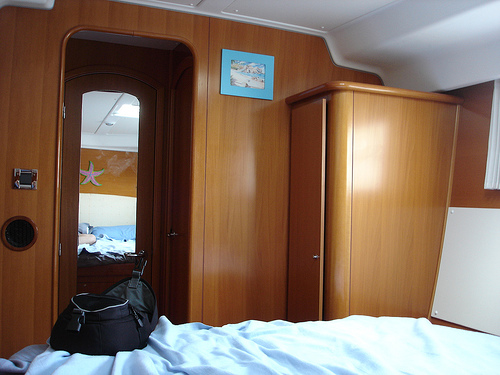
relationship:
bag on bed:
[49, 257, 159, 357] [0, 313, 499, 374]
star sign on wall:
[79, 160, 106, 187] [78, 133, 139, 226]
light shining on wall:
[234, 137, 254, 197] [0, 0, 384, 360]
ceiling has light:
[81, 89, 141, 136] [116, 103, 140, 120]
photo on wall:
[229, 58, 264, 90] [0, 0, 384, 360]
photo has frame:
[229, 58, 264, 90] [220, 48, 275, 101]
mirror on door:
[78, 88, 140, 295] [58, 71, 157, 295]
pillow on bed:
[91, 225, 137, 240] [77, 232, 137, 267]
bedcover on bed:
[24, 314, 499, 374] [0, 313, 499, 374]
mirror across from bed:
[78, 88, 140, 295] [0, 313, 499, 374]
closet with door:
[285, 80, 464, 322] [287, 98, 327, 322]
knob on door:
[312, 253, 319, 259] [287, 98, 327, 322]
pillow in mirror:
[91, 225, 137, 240] [78, 88, 140, 295]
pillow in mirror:
[77, 222, 94, 235] [78, 88, 140, 295]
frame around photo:
[220, 48, 275, 101] [229, 58, 264, 90]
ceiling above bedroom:
[1, 1, 500, 92] [1, 0, 499, 374]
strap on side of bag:
[64, 306, 86, 332] [49, 257, 159, 357]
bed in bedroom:
[0, 313, 499, 374] [1, 0, 499, 374]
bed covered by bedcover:
[0, 313, 499, 374] [24, 314, 499, 374]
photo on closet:
[229, 58, 264, 90] [158, 14, 384, 327]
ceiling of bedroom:
[1, 1, 500, 92] [1, 0, 499, 374]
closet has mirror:
[57, 37, 170, 324] [78, 88, 140, 295]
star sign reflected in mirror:
[79, 160, 106, 187] [78, 88, 140, 295]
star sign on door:
[79, 160, 106, 187] [58, 71, 157, 295]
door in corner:
[169, 65, 193, 324] [59, 37, 194, 325]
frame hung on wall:
[220, 48, 275, 101] [0, 0, 384, 360]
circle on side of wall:
[0, 215, 39, 251] [0, 0, 384, 360]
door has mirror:
[58, 71, 157, 295] [78, 88, 140, 295]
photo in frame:
[229, 58, 264, 90] [220, 48, 275, 101]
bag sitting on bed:
[49, 257, 159, 357] [0, 313, 499, 374]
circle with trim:
[0, 215, 39, 251] [1, 214, 40, 252]